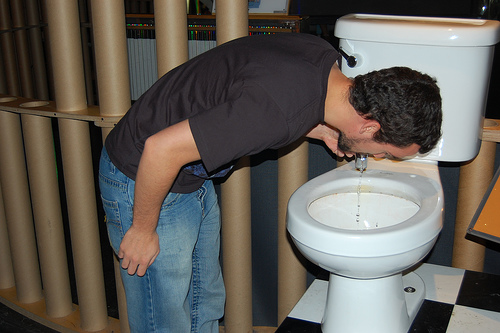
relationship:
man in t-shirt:
[92, 30, 444, 332] [103, 31, 342, 194]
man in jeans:
[92, 30, 444, 332] [97, 142, 232, 331]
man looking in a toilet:
[92, 30, 444, 332] [284, 10, 497, 331]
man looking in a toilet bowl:
[92, 30, 444, 332] [282, 162, 446, 258]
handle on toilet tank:
[335, 43, 360, 69] [328, 10, 498, 163]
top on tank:
[333, 11, 499, 48] [333, 10, 500, 166]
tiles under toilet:
[277, 260, 498, 332] [284, 10, 497, 331]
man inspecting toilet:
[92, 30, 444, 332] [284, 10, 497, 331]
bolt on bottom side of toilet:
[403, 283, 417, 297] [284, 10, 497, 331]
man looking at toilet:
[92, 30, 444, 332] [284, 10, 497, 331]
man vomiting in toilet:
[92, 30, 444, 332] [284, 10, 497, 331]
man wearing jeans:
[92, 30, 444, 332] [97, 142, 232, 331]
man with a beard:
[92, 30, 444, 332] [336, 128, 376, 157]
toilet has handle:
[284, 10, 497, 331] [335, 43, 360, 69]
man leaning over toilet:
[92, 30, 444, 332] [284, 10, 497, 331]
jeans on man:
[97, 142, 232, 331] [92, 30, 444, 332]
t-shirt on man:
[103, 31, 342, 194] [92, 30, 444, 332]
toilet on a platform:
[284, 10, 497, 331] [273, 254, 500, 330]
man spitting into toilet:
[92, 30, 444, 332] [284, 10, 497, 331]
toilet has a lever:
[284, 10, 497, 331] [334, 40, 361, 71]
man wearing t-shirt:
[92, 30, 444, 332] [103, 31, 342, 194]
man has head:
[92, 30, 444, 332] [336, 64, 445, 161]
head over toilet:
[336, 64, 445, 161] [284, 10, 497, 331]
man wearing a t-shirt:
[92, 30, 444, 332] [103, 31, 342, 194]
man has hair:
[92, 30, 444, 332] [348, 62, 444, 153]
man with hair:
[92, 30, 444, 332] [348, 62, 444, 153]